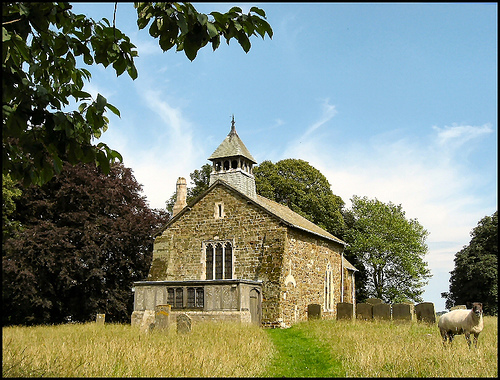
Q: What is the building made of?
A: Stone.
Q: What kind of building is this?
A: Church.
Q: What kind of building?
A: Old church.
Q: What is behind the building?
A: Trees.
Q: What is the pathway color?
A: Green.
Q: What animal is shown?
A: A sheep.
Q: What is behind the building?
A: Trees.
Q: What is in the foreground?
A: Grass.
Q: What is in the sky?
A: Clouds.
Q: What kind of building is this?
A: Church.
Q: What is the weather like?
A: Sunny.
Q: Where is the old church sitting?
A: Field.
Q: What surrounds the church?
A: Trees.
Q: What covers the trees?
A: Green leaves.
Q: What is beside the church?
A: Tombstones.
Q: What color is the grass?
A: Green.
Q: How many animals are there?
A: 1.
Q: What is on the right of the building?
A: Tombstones.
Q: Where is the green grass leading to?
A: The building.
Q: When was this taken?
A: Daytime.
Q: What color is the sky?
A: Blue.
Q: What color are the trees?
A: Green.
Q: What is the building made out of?
A: Stone.